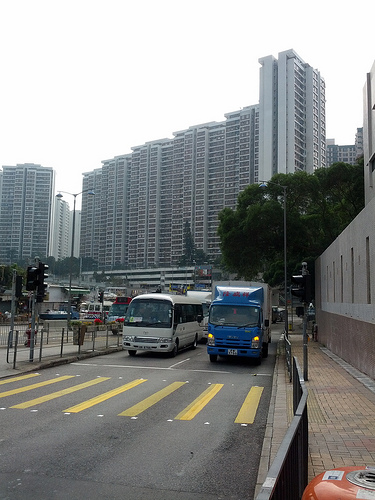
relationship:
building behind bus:
[78, 50, 326, 289] [119, 293, 205, 355]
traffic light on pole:
[25, 262, 50, 303] [30, 295, 38, 361]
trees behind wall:
[215, 153, 363, 285] [314, 194, 375, 382]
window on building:
[227, 120, 240, 125] [78, 50, 326, 289]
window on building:
[239, 133, 249, 138] [78, 50, 326, 289]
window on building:
[239, 150, 250, 155] [78, 50, 326, 289]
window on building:
[239, 173, 250, 179] [78, 50, 326, 289]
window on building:
[224, 183, 235, 189] [78, 50, 326, 289]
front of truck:
[209, 298, 264, 360] [209, 280, 272, 368]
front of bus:
[124, 294, 174, 354] [119, 293, 205, 355]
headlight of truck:
[253, 337, 260, 350] [209, 280, 272, 368]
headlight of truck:
[208, 334, 215, 344] [209, 280, 272, 368]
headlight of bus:
[158, 338, 170, 344] [119, 293, 205, 355]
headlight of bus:
[121, 336, 130, 342] [119, 293, 205, 355]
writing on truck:
[221, 289, 250, 299] [209, 280, 272, 368]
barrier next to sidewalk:
[256, 332, 307, 500] [287, 332, 375, 482]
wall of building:
[314, 194, 375, 382] [314, 60, 374, 388]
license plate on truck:
[227, 348, 239, 356] [209, 280, 272, 368]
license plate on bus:
[133, 345, 156, 350] [119, 293, 205, 355]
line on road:
[11, 376, 107, 412] [1, 303, 306, 499]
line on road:
[63, 377, 146, 416] [1, 303, 306, 499]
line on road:
[120, 379, 186, 417] [1, 303, 306, 499]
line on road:
[175, 381, 224, 422] [1, 303, 306, 499]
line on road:
[232, 382, 264, 424] [1, 303, 306, 499]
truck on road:
[209, 280, 272, 368] [1, 303, 306, 499]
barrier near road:
[256, 332, 307, 500] [1, 303, 306, 499]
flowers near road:
[94, 317, 106, 324] [1, 303, 306, 499]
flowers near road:
[114, 315, 125, 323] [1, 303, 306, 499]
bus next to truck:
[119, 293, 205, 355] [209, 280, 272, 368]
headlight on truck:
[253, 337, 260, 350] [209, 280, 272, 368]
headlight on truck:
[208, 334, 215, 344] [209, 280, 272, 368]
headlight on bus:
[121, 336, 130, 342] [119, 293, 205, 355]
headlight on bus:
[158, 338, 170, 344] [119, 293, 205, 355]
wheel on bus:
[169, 341, 181, 357] [119, 293, 205, 355]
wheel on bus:
[194, 336, 199, 349] [119, 293, 205, 355]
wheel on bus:
[128, 348, 136, 356] [119, 293, 205, 355]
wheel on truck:
[209, 354, 218, 363] [209, 280, 272, 368]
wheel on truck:
[254, 357, 262, 365] [209, 280, 272, 368]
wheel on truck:
[262, 343, 269, 357] [209, 280, 272, 368]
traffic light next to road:
[25, 262, 50, 303] [1, 303, 306, 499]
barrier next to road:
[256, 332, 307, 500] [1, 303, 306, 499]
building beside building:
[78, 50, 326, 289] [3, 162, 56, 261]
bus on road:
[119, 293, 205, 355] [1, 303, 306, 499]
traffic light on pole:
[292, 263, 312, 305] [299, 300, 310, 381]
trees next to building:
[215, 153, 363, 285] [78, 50, 326, 289]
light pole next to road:
[254, 177, 290, 339] [1, 303, 306, 499]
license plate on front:
[227, 348, 239, 356] [209, 298, 264, 360]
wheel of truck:
[209, 354, 218, 363] [209, 280, 272, 368]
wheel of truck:
[254, 357, 262, 365] [209, 280, 272, 368]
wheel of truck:
[262, 343, 269, 357] [209, 280, 272, 368]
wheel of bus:
[128, 348, 136, 356] [119, 293, 205, 355]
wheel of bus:
[169, 341, 181, 357] [119, 293, 205, 355]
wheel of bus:
[194, 336, 199, 349] [119, 293, 205, 355]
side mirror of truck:
[262, 319, 272, 331] [209, 280, 272, 368]